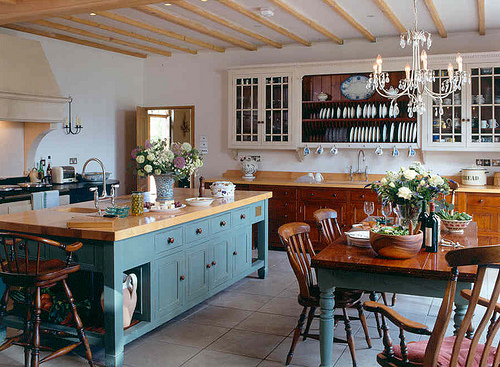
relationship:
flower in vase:
[141, 162, 156, 176] [149, 169, 178, 203]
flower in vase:
[134, 153, 146, 165] [149, 169, 178, 203]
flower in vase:
[129, 145, 144, 161] [149, 169, 178, 203]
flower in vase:
[143, 139, 157, 151] [149, 169, 178, 203]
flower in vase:
[180, 141, 192, 154] [149, 169, 178, 203]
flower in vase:
[154, 168, 165, 175] [149, 169, 178, 203]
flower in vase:
[145, 152, 159, 163] [149, 169, 178, 203]